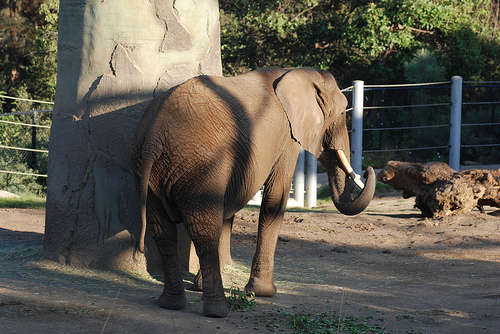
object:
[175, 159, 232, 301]
leg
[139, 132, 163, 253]
tail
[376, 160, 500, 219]
tree trunk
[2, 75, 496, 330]
cage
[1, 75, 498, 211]
fence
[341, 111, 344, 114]
eye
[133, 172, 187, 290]
leg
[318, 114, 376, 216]
trunk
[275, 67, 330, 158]
ear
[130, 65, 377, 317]
elephant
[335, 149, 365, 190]
tusks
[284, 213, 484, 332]
dirt ground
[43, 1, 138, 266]
tree trunk